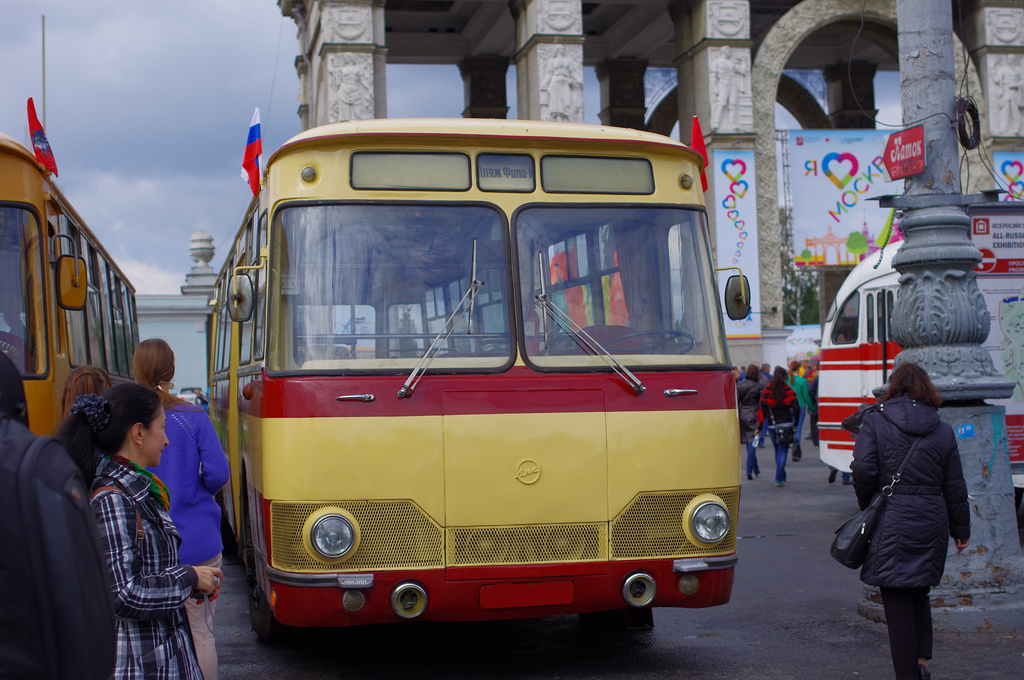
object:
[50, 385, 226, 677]
women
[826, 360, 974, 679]
women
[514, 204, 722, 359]
windshield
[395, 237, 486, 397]
windshield wiper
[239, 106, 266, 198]
flag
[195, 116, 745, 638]
bus